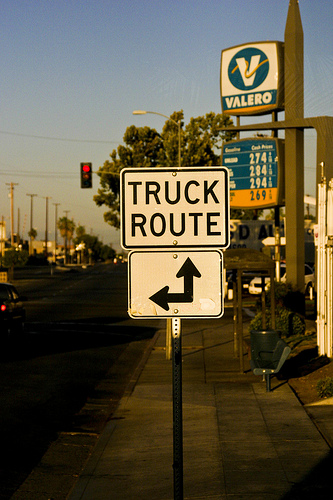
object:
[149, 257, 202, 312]
arrows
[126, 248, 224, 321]
traffic sign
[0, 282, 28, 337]
car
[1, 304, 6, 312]
light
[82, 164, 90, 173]
light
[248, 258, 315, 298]
van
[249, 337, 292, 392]
bench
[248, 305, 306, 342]
bush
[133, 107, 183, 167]
post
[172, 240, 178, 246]
screw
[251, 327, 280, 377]
trash can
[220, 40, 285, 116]
sign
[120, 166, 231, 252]
sign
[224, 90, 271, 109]
word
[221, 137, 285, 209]
sign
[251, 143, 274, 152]
gas prices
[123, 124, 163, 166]
leaves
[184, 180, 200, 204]
letter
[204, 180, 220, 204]
letter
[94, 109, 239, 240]
tree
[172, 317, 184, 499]
post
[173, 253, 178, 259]
rivet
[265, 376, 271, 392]
post